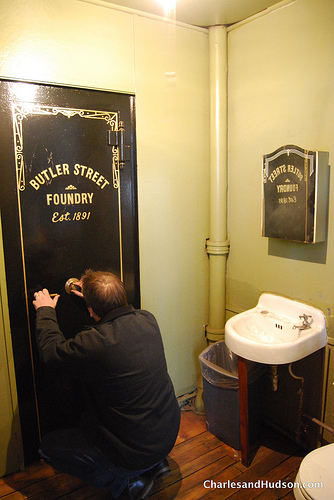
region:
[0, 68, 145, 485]
a black door in a bathroom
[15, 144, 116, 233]
toilet says Butler Street Foundry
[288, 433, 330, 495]
a toilet in a bathroom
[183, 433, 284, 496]
the floor is wood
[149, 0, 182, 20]
the light on the ceiling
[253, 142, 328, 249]
a cabinet on wall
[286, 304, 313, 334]
a faucet of silver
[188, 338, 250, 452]
a plastic bag in trash can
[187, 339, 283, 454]
trash can is plastic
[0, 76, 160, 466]
a black wall safe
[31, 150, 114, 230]
gold letters that read butler street foundry est. 1891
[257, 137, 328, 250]
a metal medicine cabinet mirror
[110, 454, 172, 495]
brown and black shoes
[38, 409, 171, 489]
a pair of blue jeans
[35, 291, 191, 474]
a black jacket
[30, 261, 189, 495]
a man trying to open a safe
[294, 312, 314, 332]
a silver water faucet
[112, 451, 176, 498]
Man is wearing shoes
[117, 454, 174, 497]
Man wearing black shoes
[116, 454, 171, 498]
Man is wearing black shoes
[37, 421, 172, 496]
Man wearing blue pants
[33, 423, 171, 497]
Man is wearing blue pants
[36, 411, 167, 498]
Man is wearing pants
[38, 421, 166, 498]
Man is wearing jeans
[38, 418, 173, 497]
Man wearing blue jeans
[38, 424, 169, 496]
Man is wearing blue jeans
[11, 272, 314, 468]
a man unlocking a safe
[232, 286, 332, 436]
a bathroom white sink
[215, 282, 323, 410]
a sink that is white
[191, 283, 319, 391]
a bathroom sink that is white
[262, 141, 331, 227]
a mirror above teh sink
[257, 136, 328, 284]
a mirror in the bathroom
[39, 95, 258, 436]
a safe in the bathroom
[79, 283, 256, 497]
a man wearing a jacket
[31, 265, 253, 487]
a man wearing a black jacket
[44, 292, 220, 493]
a man wearing pants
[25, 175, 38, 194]
The letter is beige.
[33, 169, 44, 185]
The letter is beige.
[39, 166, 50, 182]
The letter is beige.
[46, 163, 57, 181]
The letter is beige.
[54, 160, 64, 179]
The letter is beige.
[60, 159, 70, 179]
The letter is beige.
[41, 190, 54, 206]
The letter is beige.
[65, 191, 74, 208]
The letter is beige.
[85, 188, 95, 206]
The letter is beige.